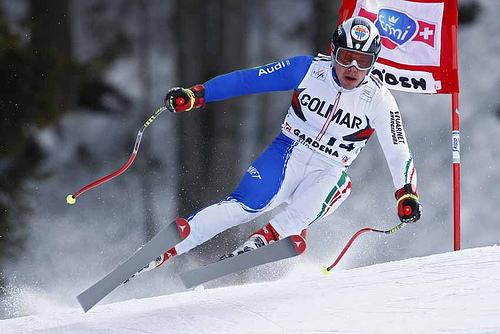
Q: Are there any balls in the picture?
A: No, there are no balls.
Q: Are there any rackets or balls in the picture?
A: No, there are no balls or rackets.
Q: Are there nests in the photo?
A: No, there are no nests.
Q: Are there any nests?
A: No, there are no nests.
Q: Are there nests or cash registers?
A: No, there are no nests or cash registers.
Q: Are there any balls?
A: No, there are no balls.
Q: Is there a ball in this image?
A: No, there are no balls.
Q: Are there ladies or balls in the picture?
A: No, there are no balls or ladies.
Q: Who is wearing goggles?
A: The athlete is wearing goggles.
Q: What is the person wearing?
A: The athlete is wearing goggles.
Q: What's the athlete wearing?
A: The athlete is wearing goggles.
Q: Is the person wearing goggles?
A: Yes, the athlete is wearing goggles.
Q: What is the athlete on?
A: The athlete is on the ski.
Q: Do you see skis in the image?
A: Yes, there are skis.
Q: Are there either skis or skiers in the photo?
A: Yes, there are skis.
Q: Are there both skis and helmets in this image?
A: Yes, there are both skis and a helmet.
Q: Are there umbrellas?
A: No, there are no umbrellas.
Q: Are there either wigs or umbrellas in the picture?
A: No, there are no umbrellas or wigs.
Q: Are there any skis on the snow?
A: Yes, there are skis on the snow.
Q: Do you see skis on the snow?
A: Yes, there are skis on the snow.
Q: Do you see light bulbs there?
A: No, there are no light bulbs.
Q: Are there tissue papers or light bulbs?
A: No, there are no light bulbs or tissue papers.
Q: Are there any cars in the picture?
A: No, there are no cars.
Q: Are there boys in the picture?
A: No, there are no boys.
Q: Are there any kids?
A: No, there are no kids.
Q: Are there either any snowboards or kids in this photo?
A: No, there are no kids or snowboards.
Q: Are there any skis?
A: Yes, there are skis.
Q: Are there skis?
A: Yes, there are skis.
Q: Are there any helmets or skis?
A: Yes, there are skis.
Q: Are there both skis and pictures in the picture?
A: No, there are skis but no pictures.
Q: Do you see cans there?
A: No, there are no cans.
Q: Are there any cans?
A: No, there are no cans.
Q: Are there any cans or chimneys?
A: No, there are no cans or chimneys.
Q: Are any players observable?
A: No, there are no players.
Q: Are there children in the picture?
A: No, there are no children.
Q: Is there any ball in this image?
A: No, there are no balls.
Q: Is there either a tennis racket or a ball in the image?
A: No, there are no balls or rackets.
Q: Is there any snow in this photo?
A: Yes, there is snow.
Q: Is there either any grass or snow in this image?
A: Yes, there is snow.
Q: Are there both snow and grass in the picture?
A: No, there is snow but no grass.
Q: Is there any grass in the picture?
A: No, there is no grass.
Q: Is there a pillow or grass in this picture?
A: No, there are no grass or pillows.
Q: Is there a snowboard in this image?
A: No, there are no snowboards.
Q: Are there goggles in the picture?
A: Yes, there are goggles.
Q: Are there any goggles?
A: Yes, there are goggles.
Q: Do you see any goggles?
A: Yes, there are goggles.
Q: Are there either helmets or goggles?
A: Yes, there are goggles.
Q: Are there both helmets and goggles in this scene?
A: Yes, there are both goggles and a helmet.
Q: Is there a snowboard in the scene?
A: No, there are no snowboards.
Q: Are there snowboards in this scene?
A: No, there are no snowboards.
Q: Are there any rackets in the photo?
A: No, there are no rackets.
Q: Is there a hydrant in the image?
A: No, there are no fire hydrants.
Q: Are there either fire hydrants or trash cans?
A: No, there are no fire hydrants or trash cans.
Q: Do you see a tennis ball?
A: No, there are no tennis balls.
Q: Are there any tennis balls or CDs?
A: No, there are no tennis balls or cds.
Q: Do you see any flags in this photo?
A: Yes, there is a flag.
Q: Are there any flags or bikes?
A: Yes, there is a flag.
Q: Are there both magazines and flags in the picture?
A: No, there is a flag but no magazines.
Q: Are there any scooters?
A: No, there are no scooters.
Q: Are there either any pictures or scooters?
A: No, there are no scooters or pictures.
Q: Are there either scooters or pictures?
A: No, there are no scooters or pictures.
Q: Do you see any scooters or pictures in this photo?
A: No, there are no scooters or pictures.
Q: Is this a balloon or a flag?
A: This is a flag.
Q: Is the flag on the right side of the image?
A: Yes, the flag is on the right of the image.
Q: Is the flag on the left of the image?
A: No, the flag is on the right of the image.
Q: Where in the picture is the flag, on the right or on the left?
A: The flag is on the right of the image.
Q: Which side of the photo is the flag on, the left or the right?
A: The flag is on the right of the image.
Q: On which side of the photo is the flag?
A: The flag is on the right of the image.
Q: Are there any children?
A: No, there are no children.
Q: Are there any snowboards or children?
A: No, there are no children or snowboards.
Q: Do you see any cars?
A: No, there are no cars.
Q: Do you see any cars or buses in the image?
A: No, there are no cars or buses.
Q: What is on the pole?
A: The sign is on the pole.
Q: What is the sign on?
A: The sign is on the pole.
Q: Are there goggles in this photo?
A: Yes, there are goggles.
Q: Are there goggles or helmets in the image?
A: Yes, there are goggles.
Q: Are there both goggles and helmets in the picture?
A: Yes, there are both goggles and a helmet.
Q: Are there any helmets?
A: Yes, there is a helmet.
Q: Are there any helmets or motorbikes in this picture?
A: Yes, there is a helmet.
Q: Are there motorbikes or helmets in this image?
A: Yes, there is a helmet.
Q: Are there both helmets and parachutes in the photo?
A: No, there is a helmet but no parachutes.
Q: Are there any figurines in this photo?
A: No, there are no figurines.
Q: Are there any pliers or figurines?
A: No, there are no figurines or pliers.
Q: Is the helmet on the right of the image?
A: Yes, the helmet is on the right of the image.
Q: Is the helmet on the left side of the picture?
A: No, the helmet is on the right of the image.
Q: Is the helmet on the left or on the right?
A: The helmet is on the right of the image.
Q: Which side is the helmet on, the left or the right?
A: The helmet is on the right of the image.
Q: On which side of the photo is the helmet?
A: The helmet is on the right of the image.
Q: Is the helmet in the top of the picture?
A: Yes, the helmet is in the top of the image.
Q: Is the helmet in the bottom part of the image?
A: No, the helmet is in the top of the image.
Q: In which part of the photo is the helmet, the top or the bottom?
A: The helmet is in the top of the image.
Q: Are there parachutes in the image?
A: No, there are no parachutes.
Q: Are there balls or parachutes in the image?
A: No, there are no parachutes or balls.